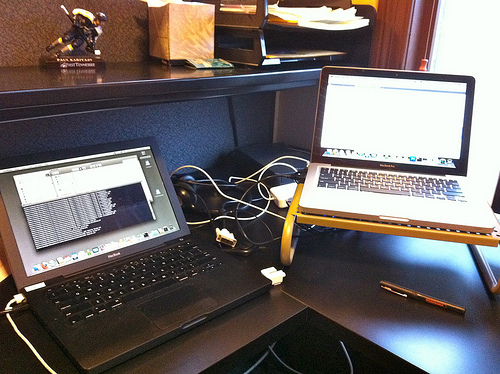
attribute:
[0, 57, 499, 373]
station — wooden, black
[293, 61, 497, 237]
computer — laptop, on, silver, white, black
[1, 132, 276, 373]
computer — black, on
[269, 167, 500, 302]
table — yellow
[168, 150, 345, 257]
cords — messy, white and black, white, long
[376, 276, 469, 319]
pen — black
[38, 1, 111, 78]
trophy — small, gold, player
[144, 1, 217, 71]
box — opened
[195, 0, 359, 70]
basket — 2 tiered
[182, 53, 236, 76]
booklet — small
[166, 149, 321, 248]
cable — white, long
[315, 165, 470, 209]
buttons — black, small, many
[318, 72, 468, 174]
screen — on